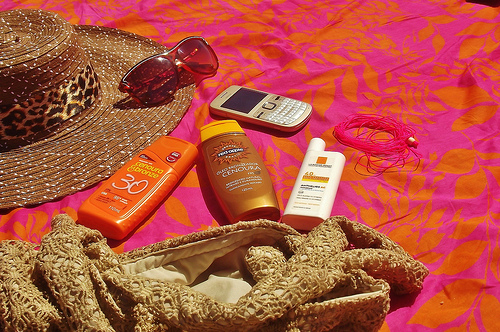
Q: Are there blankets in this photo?
A: Yes, there is a blanket.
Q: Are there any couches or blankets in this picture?
A: Yes, there is a blanket.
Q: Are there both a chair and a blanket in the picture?
A: No, there is a blanket but no chairs.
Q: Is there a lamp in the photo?
A: No, there are no lamps.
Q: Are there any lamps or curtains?
A: No, there are no lamps or curtains.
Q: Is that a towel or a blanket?
A: That is a blanket.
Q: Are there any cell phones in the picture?
A: Yes, there is a cell phone.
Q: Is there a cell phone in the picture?
A: Yes, there is a cell phone.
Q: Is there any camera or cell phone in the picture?
A: Yes, there is a cell phone.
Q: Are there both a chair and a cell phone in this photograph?
A: No, there is a cell phone but no chairs.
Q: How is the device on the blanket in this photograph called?
A: The device is a cell phone.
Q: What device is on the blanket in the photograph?
A: The device is a cell phone.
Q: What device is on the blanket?
A: The device is a cell phone.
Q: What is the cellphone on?
A: The cellphone is on the blanket.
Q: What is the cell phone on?
A: The cellphone is on the blanket.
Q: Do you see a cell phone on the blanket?
A: Yes, there is a cell phone on the blanket.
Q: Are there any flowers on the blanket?
A: No, there is a cell phone on the blanket.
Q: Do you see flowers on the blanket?
A: No, there is a cell phone on the blanket.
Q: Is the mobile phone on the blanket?
A: Yes, the mobile phone is on the blanket.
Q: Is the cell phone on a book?
A: No, the cell phone is on the blanket.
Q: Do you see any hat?
A: Yes, there is a hat.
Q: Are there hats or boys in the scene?
A: Yes, there is a hat.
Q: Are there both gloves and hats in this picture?
A: No, there is a hat but no gloves.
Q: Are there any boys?
A: No, there are no boys.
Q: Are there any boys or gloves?
A: No, there are no boys or gloves.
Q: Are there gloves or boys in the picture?
A: No, there are no boys or gloves.